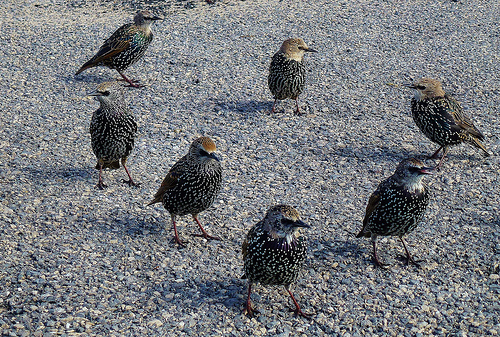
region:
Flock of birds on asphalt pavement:
[67, 3, 491, 321]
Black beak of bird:
[294, 213, 311, 230]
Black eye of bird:
[102, 87, 112, 102]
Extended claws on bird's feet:
[234, 298, 318, 322]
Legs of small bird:
[236, 278, 311, 322]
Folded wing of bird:
[95, 18, 141, 65]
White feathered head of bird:
[277, 33, 305, 58]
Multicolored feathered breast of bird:
[91, 108, 128, 160]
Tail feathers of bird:
[72, 52, 97, 78]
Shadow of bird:
[218, 87, 284, 122]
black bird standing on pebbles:
[86, 0, 172, 79]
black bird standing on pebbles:
[74, 89, 142, 191]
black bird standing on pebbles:
[140, 131, 223, 243]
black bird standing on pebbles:
[235, 190, 309, 296]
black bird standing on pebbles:
[252, 20, 316, 117]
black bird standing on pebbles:
[346, 139, 438, 259]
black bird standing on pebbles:
[398, 55, 477, 162]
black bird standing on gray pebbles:
[161, 123, 227, 248]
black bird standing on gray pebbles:
[65, 75, 166, 177]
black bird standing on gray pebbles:
[241, 9, 342, 141]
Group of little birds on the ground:
[71, 8, 491, 320]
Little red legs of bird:
[244, 284, 305, 310]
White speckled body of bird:
[242, 230, 310, 285]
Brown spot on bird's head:
[196, 135, 213, 150]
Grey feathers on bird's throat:
[404, 164, 425, 191]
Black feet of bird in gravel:
[363, 255, 424, 269]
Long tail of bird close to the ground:
[458, 118, 494, 155]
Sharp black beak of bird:
[305, 46, 317, 53]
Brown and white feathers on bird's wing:
[92, 33, 136, 62]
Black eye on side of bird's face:
[101, 89, 112, 96]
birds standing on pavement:
[88, 8, 492, 315]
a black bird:
[243, 208, 319, 318]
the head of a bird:
[191, 136, 227, 161]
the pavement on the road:
[263, 124, 355, 179]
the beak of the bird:
[416, 165, 436, 174]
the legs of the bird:
[168, 212, 217, 244]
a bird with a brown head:
[153, 135, 224, 250]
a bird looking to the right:
[83, 82, 141, 185]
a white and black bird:
[356, 153, 436, 275]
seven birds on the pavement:
[73, 10, 490, 318]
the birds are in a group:
[73, 50, 460, 315]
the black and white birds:
[137, 154, 335, 328]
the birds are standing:
[78, 99, 326, 304]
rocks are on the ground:
[32, 220, 207, 285]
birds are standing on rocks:
[157, 146, 319, 254]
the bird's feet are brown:
[233, 286, 361, 323]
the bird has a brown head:
[185, 134, 239, 161]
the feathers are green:
[112, 30, 174, 56]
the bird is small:
[246, 27, 355, 163]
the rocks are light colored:
[17, 5, 89, 33]